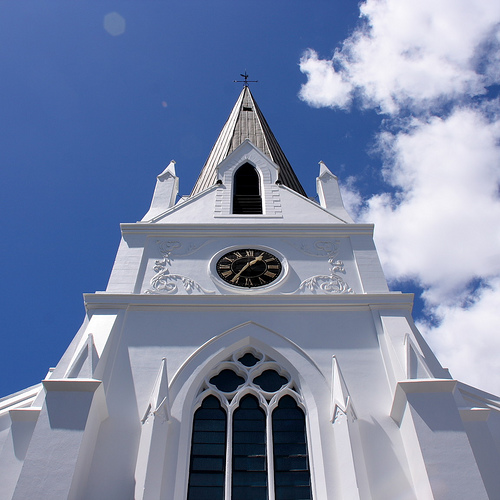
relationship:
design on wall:
[285, 251, 357, 295] [88, 192, 413, 313]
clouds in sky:
[284, 2, 499, 379] [6, 3, 499, 422]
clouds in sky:
[430, 199, 494, 254] [16, 11, 481, 311]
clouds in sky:
[375, 69, 454, 160] [29, 30, 184, 115]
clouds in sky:
[300, 2, 497, 116] [1, 1, 498, 71]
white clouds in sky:
[390, 9, 454, 88] [267, 10, 479, 161]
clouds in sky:
[284, 2, 499, 379] [0, 2, 497, 380]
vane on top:
[231, 68, 262, 85] [231, 63, 281, 115]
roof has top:
[201, 85, 303, 192] [231, 63, 281, 115]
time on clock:
[199, 240, 280, 291] [213, 243, 284, 289]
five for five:
[258, 276, 266, 284] [256, 273, 265, 284]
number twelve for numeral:
[245, 250, 255, 257] [244, 252, 253, 262]